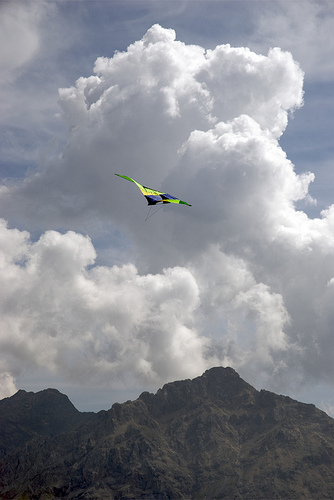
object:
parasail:
[115, 173, 192, 221]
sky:
[44, 74, 93, 146]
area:
[131, 366, 333, 498]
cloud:
[0, 22, 315, 258]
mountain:
[0, 365, 333, 499]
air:
[31, 1, 311, 69]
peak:
[0, 365, 261, 414]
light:
[170, 37, 206, 82]